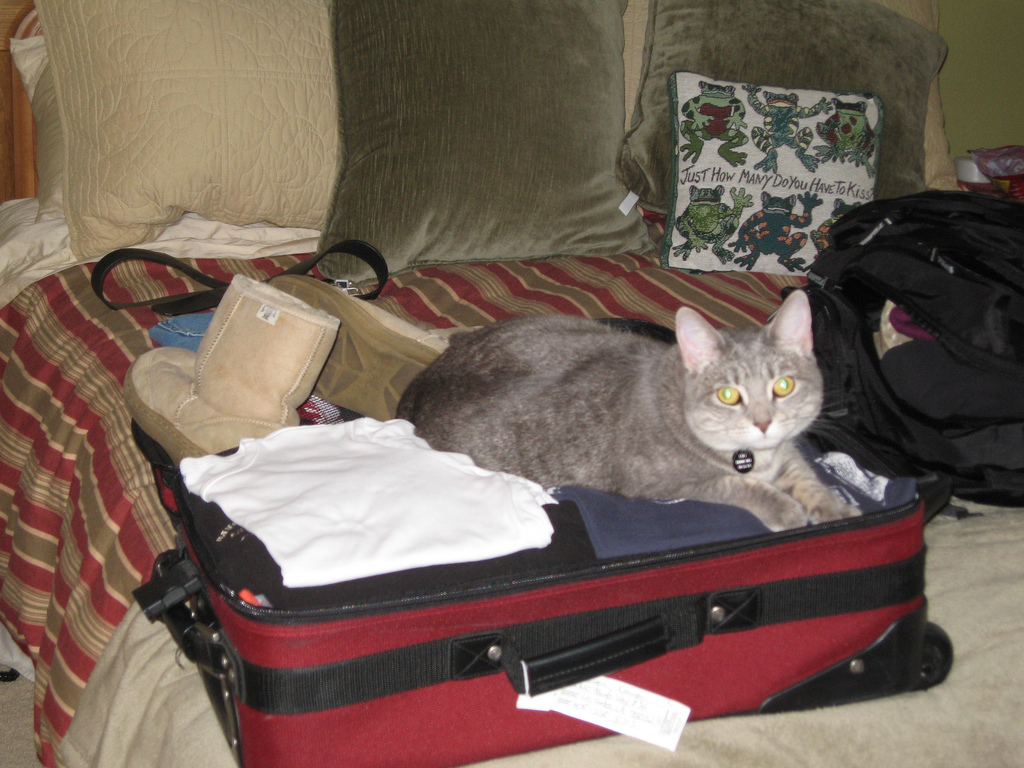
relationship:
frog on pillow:
[681, 77, 759, 194] [660, 66, 885, 278]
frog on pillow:
[736, 75, 827, 169] [660, 66, 885, 278]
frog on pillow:
[803, 92, 873, 175] [660, 66, 885, 278]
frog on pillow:
[669, 174, 754, 267] [660, 66, 885, 278]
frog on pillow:
[733, 172, 822, 278] [660, 66, 885, 278]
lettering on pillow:
[677, 165, 874, 209] [660, 66, 885, 278]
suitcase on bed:
[128, 425, 956, 765] [5, 3, 1023, 766]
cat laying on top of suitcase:
[396, 284, 865, 531] [128, 425, 956, 765]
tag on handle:
[515, 660, 693, 753] [455, 585, 764, 681]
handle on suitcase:
[455, 585, 764, 681] [128, 425, 956, 765]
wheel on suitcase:
[898, 621, 955, 691] [128, 425, 956, 765]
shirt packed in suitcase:
[180, 414, 561, 589] [128, 425, 956, 765]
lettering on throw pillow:
[679, 165, 876, 205] [664, 66, 889, 278]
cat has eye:
[396, 284, 865, 531] [768, 369, 803, 408]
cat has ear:
[396, 284, 865, 531] [671, 300, 728, 374]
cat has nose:
[396, 284, 865, 531] [751, 407, 775, 433]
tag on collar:
[729, 444, 760, 477] [696, 442, 803, 449]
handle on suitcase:
[446, 578, 769, 691] [128, 425, 956, 765]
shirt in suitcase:
[191, 502, 593, 606] [128, 425, 956, 765]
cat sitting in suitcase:
[396, 284, 865, 531] [128, 425, 956, 765]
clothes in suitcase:
[178, 412, 913, 588] [128, 425, 956, 765]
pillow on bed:
[660, 66, 885, 278] [5, 3, 1023, 766]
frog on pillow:
[681, 75, 751, 168] [660, 66, 885, 278]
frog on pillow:
[744, 84, 831, 178] [660, 66, 885, 278]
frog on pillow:
[796, 92, 877, 175] [660, 66, 885, 278]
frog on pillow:
[729, 187, 827, 272] [660, 66, 885, 278]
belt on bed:
[90, 243, 391, 317] [5, 3, 1023, 766]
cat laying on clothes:
[396, 284, 865, 531] [178, 412, 913, 588]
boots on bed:
[124, 271, 449, 462] [5, 3, 1023, 766]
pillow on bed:
[33, 1, 342, 267] [5, 3, 1023, 766]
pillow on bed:
[314, 4, 660, 279] [5, 3, 1023, 766]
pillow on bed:
[610, 1, 950, 216] [5, 3, 1023, 766]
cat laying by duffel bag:
[396, 284, 865, 531] [807, 183, 1022, 519]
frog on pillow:
[677, 73, 753, 169] [660, 66, 885, 278]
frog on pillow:
[738, 83, 832, 176] [660, 66, 885, 278]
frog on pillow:
[807, 88, 881, 179] [660, 66, 885, 278]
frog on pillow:
[669, 179, 749, 264] [660, 66, 885, 278]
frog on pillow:
[733, 181, 822, 274] [660, 66, 885, 278]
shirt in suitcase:
[180, 414, 561, 589] [128, 425, 956, 765]